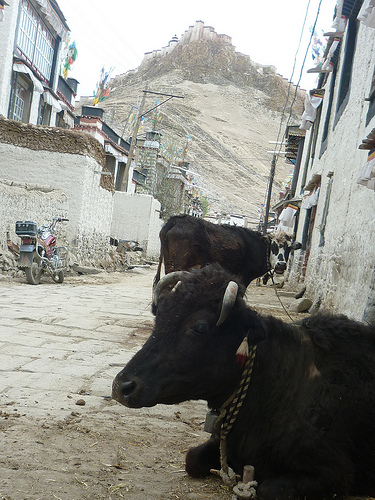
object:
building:
[0, 0, 73, 130]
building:
[279, 0, 375, 322]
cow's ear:
[235, 307, 266, 347]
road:
[2, 262, 314, 499]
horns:
[154, 270, 189, 306]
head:
[111, 260, 244, 410]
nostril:
[121, 381, 137, 397]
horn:
[217, 279, 236, 329]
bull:
[110, 264, 373, 497]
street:
[1, 266, 212, 498]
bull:
[152, 214, 303, 305]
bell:
[202, 408, 223, 433]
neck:
[218, 314, 295, 418]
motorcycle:
[16, 214, 69, 283]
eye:
[191, 321, 214, 336]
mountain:
[138, 16, 280, 102]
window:
[9, 79, 24, 122]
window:
[38, 102, 46, 122]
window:
[11, 0, 53, 83]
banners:
[273, 196, 305, 213]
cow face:
[270, 234, 290, 275]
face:
[111, 277, 217, 410]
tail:
[151, 243, 162, 290]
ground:
[0, 283, 113, 492]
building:
[1, 122, 113, 265]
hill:
[94, 19, 303, 156]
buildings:
[140, 19, 229, 62]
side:
[283, 32, 374, 332]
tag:
[234, 336, 249, 369]